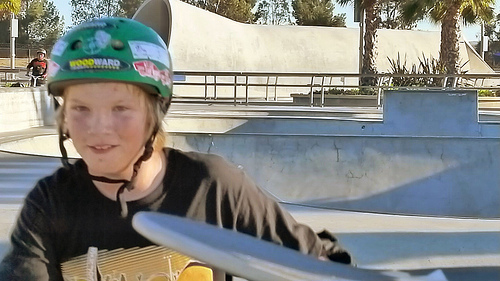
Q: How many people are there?
A: Two.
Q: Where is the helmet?
A: On the boy's head.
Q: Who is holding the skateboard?
A: The boy.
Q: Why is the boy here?
A: To skateboard.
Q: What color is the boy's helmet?
A: Green.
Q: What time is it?
A: Daytime.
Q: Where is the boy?
A: A skatepark.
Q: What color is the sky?
A: Blue.